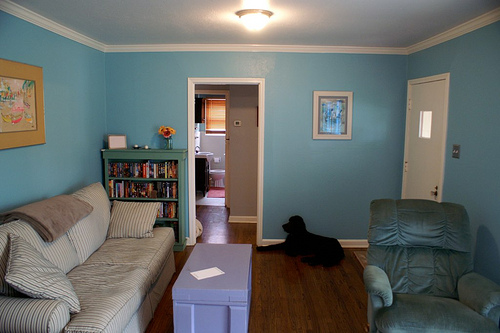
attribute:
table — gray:
[165, 237, 260, 324]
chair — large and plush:
[358, 193, 498, 331]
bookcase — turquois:
[100, 146, 189, 253]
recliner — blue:
[354, 189, 485, 331]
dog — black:
[253, 213, 347, 270]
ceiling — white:
[2, 2, 498, 54]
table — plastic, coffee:
[173, 243, 252, 332]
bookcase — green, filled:
[95, 141, 209, 245]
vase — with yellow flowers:
[163, 135, 174, 146]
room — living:
[2, 3, 499, 328]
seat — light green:
[360, 192, 497, 331]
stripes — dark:
[0, 184, 178, 331]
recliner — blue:
[359, 194, 498, 331]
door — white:
[395, 70, 453, 201]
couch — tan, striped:
[9, 202, 146, 329]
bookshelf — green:
[101, 147, 187, 251]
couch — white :
[0, 183, 177, 331]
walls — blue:
[267, 82, 321, 162]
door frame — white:
[174, 65, 274, 250]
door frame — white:
[397, 60, 453, 225]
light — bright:
[232, 8, 271, 32]